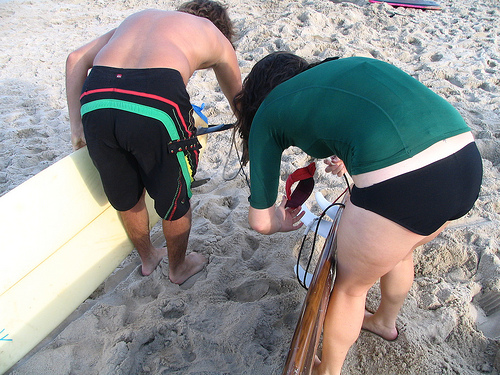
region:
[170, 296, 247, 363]
the sand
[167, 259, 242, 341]
the sand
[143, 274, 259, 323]
the sand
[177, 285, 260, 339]
the sand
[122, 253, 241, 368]
the sand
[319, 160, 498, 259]
The girl has black bottoms on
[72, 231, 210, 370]
The man is barefoot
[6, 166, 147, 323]
The surfboard is white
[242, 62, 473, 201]
The girl has a green shirt on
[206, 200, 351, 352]
The sand is tan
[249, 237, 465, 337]
The girl has a surfboard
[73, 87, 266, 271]
The man has stripes on his bottoms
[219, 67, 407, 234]
The girl's hair is down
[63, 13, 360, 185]
The man has no shirt on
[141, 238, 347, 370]
The sand has prints in it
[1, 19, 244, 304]
a man holding a surf board up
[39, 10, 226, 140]
a man with no shirt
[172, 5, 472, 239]
a woman wearing a green shirt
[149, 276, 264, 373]
tracks in the sand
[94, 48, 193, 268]
a man wearing striped shorts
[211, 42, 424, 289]
a woman bent over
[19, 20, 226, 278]
a man bent over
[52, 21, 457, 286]
two people standing in the sand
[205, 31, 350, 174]
a woman with brown hair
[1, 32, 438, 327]
two people with surf boards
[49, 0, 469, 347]
Two people on the beach.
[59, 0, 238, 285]
The person on the left is a man.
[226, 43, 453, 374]
Person on the right is a woman.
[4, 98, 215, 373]
White surfboard on the right.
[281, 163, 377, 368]
Brown, wooden surfboard on the right.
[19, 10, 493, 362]
The sand is brown.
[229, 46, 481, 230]
Woman has a green top on.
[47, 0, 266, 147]
The man is shirtless.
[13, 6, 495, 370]
Photo taken in the summer.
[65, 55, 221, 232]
Blue and red stripes on the black shorts.